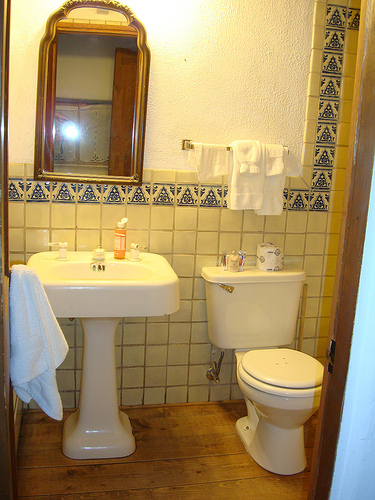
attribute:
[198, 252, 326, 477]
toilet — white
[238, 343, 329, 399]
lid — down, closed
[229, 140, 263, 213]
towel — hanging, hanging up, white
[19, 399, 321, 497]
floor — wooden, hardwood, light brown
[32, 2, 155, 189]
mirror — gold framed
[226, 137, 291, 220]
towels — white, hanging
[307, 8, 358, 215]
tiles — yellow, white, blue, decorative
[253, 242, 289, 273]
toilet paper — roll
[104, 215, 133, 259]
bottle — open, orange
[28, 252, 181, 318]
sink — white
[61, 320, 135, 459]
pedestal — white